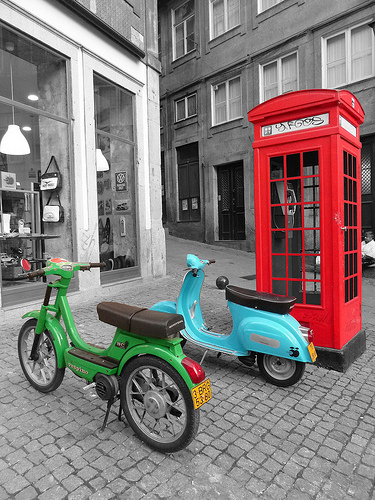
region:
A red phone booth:
[237, 82, 372, 366]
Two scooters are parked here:
[14, 244, 336, 457]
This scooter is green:
[18, 251, 207, 450]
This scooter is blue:
[159, 242, 321, 384]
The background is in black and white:
[11, 2, 246, 250]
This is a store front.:
[2, 18, 159, 284]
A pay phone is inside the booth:
[268, 179, 301, 240]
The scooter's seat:
[96, 295, 192, 339]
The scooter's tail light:
[179, 351, 211, 385]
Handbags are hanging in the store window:
[34, 152, 67, 230]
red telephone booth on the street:
[246, 88, 370, 373]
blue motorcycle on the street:
[147, 252, 319, 388]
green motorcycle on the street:
[14, 262, 213, 454]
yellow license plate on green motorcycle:
[185, 376, 213, 408]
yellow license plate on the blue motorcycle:
[304, 342, 319, 363]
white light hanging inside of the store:
[0, 50, 32, 157]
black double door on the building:
[212, 157, 248, 251]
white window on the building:
[206, 70, 244, 124]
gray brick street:
[5, 230, 367, 495]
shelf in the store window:
[0, 185, 48, 292]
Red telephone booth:
[241, 87, 367, 283]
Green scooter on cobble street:
[19, 258, 181, 438]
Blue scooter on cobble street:
[192, 252, 253, 374]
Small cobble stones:
[244, 396, 329, 487]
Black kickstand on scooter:
[89, 397, 139, 440]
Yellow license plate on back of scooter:
[188, 380, 223, 407]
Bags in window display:
[33, 150, 74, 234]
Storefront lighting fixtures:
[5, 69, 37, 181]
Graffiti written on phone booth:
[259, 86, 371, 149]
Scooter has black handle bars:
[179, 252, 221, 279]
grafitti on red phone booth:
[256, 115, 335, 133]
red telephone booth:
[232, 91, 373, 305]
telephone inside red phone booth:
[272, 185, 306, 217]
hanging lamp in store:
[3, 102, 34, 163]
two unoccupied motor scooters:
[18, 244, 320, 462]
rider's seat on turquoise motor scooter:
[184, 276, 323, 315]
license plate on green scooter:
[188, 375, 216, 411]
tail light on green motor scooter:
[176, 345, 205, 388]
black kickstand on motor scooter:
[90, 376, 128, 431]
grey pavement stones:
[238, 415, 349, 495]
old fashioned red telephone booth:
[248, 88, 363, 369]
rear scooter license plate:
[187, 379, 212, 408]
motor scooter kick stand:
[98, 398, 128, 432]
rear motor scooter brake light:
[177, 354, 207, 385]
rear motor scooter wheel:
[255, 349, 305, 387]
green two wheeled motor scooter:
[23, 258, 205, 459]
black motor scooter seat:
[89, 297, 187, 340]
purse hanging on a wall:
[39, 156, 61, 189]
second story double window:
[205, 77, 248, 126]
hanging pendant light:
[4, 43, 27, 158]